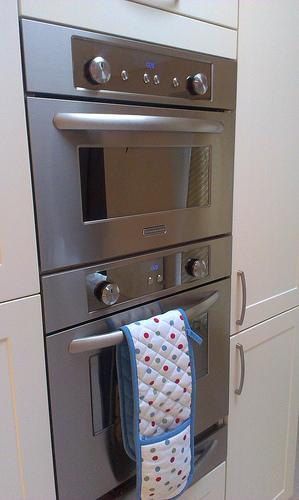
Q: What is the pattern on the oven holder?
A: Polka dots.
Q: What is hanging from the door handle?
A: Pot holder.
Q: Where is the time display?
A: Above the oven doors.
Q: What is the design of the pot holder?
A: Polka dots.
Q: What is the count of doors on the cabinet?
A: 2.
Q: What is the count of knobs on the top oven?
A: 2.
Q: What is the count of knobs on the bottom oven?
A: 2.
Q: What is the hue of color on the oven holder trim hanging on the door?
A: Blue.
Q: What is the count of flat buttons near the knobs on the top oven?
A: 4.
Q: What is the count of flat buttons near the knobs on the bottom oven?
A: 2.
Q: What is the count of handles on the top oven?
A: 1.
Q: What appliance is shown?
A: Ovens.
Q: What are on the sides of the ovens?
A: Cabinets.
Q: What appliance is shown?
A: Oven.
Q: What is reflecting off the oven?
A: Window blinds.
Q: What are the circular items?
A: Dials.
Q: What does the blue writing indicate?
A: The time.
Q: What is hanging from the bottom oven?
A: Pot holder.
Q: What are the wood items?
A: Cupboard doors.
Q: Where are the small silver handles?
A: On cupboards.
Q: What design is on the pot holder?
A: Polka dots.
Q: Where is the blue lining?
A: On pot holder.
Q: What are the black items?
A: Windows of the ovens.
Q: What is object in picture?
A: Oven.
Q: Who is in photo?
A: Noone.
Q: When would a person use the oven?
A: When baking.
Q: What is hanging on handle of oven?
A: Oven mitt.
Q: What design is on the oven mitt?
A: Circles.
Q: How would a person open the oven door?
A: By handle.